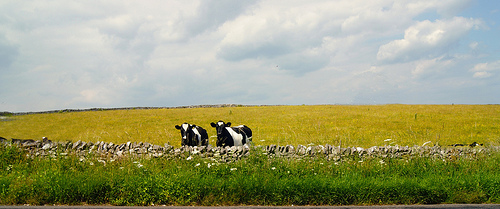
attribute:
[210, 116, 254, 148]
cow —  Two, present, adult, black, white, chill, thinking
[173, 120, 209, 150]
cow — black, small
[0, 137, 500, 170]
wall — rocky, long, low, stone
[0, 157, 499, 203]
grass — tall, weedy, green, dark, yellow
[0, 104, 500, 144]
field — large, yellow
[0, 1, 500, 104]
sky — blue, gray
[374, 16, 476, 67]
cloud — white, puffy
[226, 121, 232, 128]
ear — black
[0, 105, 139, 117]
trees — green